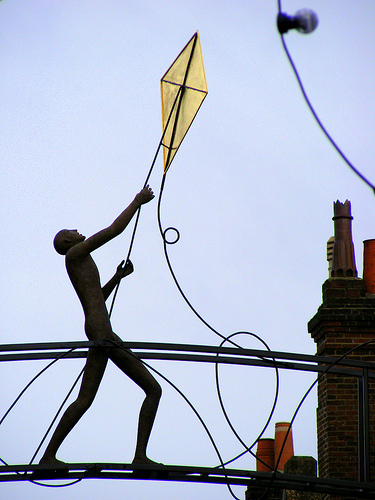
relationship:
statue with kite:
[34, 184, 170, 470] [156, 30, 209, 177]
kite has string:
[156, 30, 209, 177] [1, 90, 365, 500]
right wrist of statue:
[127, 195, 143, 207] [34, 184, 170, 470]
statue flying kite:
[34, 184, 170, 470] [156, 30, 209, 177]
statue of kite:
[34, 184, 170, 470] [156, 30, 209, 177]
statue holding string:
[34, 184, 170, 470] [1, 90, 365, 500]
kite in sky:
[156, 30, 209, 177] [3, 1, 370, 500]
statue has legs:
[34, 184, 170, 470] [91, 329, 171, 469]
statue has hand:
[34, 184, 170, 470] [134, 182, 157, 205]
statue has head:
[34, 184, 170, 470] [45, 226, 87, 260]